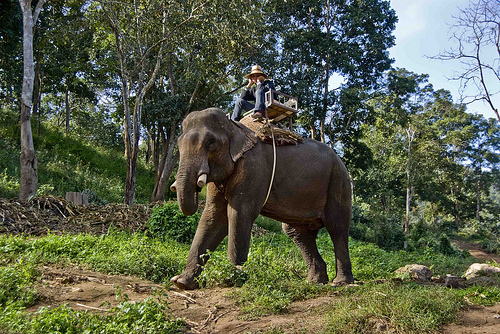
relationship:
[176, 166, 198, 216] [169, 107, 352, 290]
nose tucked under elephant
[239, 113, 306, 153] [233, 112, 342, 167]
blanket folded on back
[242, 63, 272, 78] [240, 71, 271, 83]
hat on head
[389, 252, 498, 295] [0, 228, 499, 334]
log on dirt path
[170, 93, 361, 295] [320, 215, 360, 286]
elephant has leg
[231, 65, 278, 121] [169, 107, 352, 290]
man on elephant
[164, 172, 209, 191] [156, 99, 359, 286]
tusk attached to elephant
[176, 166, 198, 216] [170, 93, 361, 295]
nose belonging to elephant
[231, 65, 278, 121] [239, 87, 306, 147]
man sitting in seat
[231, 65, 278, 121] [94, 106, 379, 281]
man sitting on elephant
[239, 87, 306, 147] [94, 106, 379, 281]
seat attached to elephant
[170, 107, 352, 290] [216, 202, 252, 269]
elephant has leg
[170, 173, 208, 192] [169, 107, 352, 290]
tusk of elephant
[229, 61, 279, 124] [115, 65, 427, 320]
man riding elephant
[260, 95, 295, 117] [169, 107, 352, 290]
seat on back of elephant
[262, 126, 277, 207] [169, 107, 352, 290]
rope under elephant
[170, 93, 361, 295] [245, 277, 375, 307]
elephant walking in grass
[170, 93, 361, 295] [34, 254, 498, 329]
elephant walking in dirt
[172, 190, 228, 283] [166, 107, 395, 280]
leg of an elephant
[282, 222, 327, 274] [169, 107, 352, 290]
leg of an elephant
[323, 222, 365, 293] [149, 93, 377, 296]
leg of an elephant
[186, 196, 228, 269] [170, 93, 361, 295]
leg of an elephant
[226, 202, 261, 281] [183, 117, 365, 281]
leg of an elephant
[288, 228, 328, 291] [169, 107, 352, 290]
leg of an elephant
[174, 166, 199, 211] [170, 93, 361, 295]
nose of an elephant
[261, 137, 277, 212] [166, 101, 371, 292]
rope around elephant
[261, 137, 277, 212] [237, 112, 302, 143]
rope holding seat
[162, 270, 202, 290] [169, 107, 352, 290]
foot of elephant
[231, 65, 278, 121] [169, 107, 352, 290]
man riding an elephant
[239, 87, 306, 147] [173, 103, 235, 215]
seat on elephant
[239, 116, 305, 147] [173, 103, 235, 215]
blanket on elephant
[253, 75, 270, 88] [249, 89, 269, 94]
elbows on knees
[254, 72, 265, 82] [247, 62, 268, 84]
hands on face